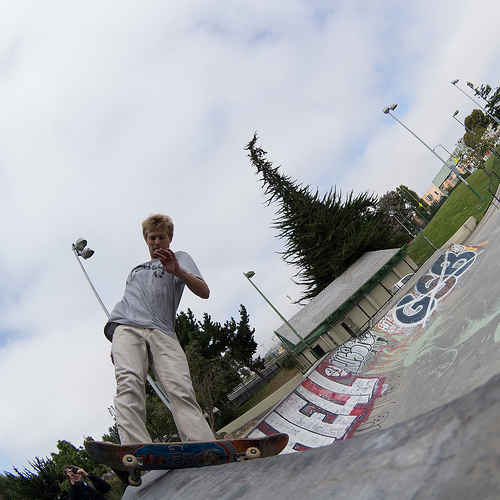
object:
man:
[106, 209, 221, 442]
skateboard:
[84, 429, 288, 488]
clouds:
[0, 0, 499, 472]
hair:
[142, 212, 173, 234]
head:
[142, 212, 175, 256]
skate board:
[83, 432, 290, 486]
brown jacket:
[83, 425, 291, 487]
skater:
[105, 210, 217, 443]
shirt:
[104, 248, 204, 338]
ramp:
[123, 183, 497, 499]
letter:
[414, 272, 459, 298]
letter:
[393, 292, 437, 327]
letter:
[303, 367, 378, 400]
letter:
[273, 390, 358, 441]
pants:
[107, 322, 217, 452]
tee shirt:
[103, 250, 204, 339]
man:
[58, 458, 103, 492]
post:
[69, 237, 173, 412]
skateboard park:
[110, 148, 500, 500]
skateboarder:
[103, 213, 220, 442]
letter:
[430, 248, 478, 277]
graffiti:
[250, 309, 441, 476]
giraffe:
[83, 429, 291, 487]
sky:
[0, 3, 496, 483]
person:
[62, 462, 117, 497]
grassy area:
[403, 144, 497, 275]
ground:
[125, 217, 497, 499]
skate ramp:
[236, 245, 500, 479]